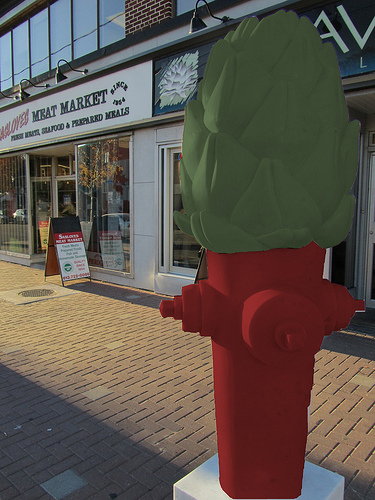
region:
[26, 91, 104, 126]
the words MEAT MARKET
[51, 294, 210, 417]
the brick sidewalk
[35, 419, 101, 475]
the shade on the sidewalk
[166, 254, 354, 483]
the red hydrant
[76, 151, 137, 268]
the glass window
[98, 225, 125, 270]
the reflection in the window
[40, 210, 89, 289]
the sign by the window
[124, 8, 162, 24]
the red brick on the building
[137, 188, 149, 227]
the white part of the building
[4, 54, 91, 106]
the black lights on the building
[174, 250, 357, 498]
red hydrant on white base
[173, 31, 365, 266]
artichoke on top of hydrant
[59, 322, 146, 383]
tan bricks in sidewalk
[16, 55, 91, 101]
lights on curved poles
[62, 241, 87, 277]
words on white sign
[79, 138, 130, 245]
reflection on store window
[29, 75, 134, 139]
words on white sign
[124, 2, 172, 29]
red bricks on building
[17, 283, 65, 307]
manhole cover in sidewalk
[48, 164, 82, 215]
glass door on storefront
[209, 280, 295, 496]
a water pipe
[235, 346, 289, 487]
a water pipe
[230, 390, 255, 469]
a water pipe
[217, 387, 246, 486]
a water pipe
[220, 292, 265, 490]
a water pipe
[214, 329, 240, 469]
a water pipe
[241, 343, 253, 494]
a water pipe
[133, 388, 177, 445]
part of a floor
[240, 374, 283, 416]
part of a tower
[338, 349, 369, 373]
edge of a shade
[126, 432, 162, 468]
part of a shade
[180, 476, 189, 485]
base of a tower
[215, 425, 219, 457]
edge of a pillar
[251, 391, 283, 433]
side of a pillar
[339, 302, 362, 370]
edge of a tank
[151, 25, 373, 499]
large photoshopped fire hydrant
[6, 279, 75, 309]
round manhole on sidewalk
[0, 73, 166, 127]
"meat market" sign above store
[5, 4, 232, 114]
street lamps above sidewalk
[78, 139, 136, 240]
reflection of tree in window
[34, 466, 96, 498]
white brick among red bricks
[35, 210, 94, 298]
portable red and white sign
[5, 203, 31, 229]
reflection of car in window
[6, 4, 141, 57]
row of window on building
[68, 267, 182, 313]
shadow of portable sign